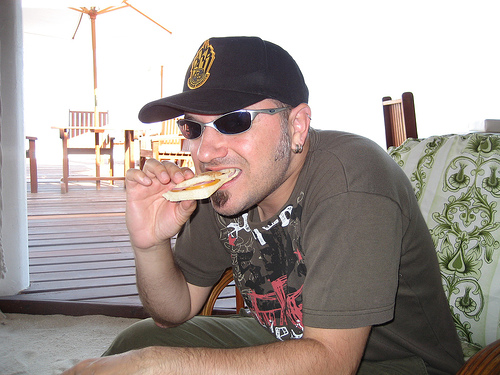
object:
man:
[60, 35, 463, 374]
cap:
[137, 36, 310, 124]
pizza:
[161, 169, 240, 202]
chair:
[60, 106, 116, 192]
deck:
[0, 177, 259, 313]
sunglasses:
[178, 108, 291, 139]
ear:
[290, 104, 312, 154]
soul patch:
[212, 191, 230, 207]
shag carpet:
[0, 313, 143, 375]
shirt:
[174, 128, 466, 371]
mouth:
[200, 167, 240, 184]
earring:
[295, 144, 305, 154]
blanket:
[387, 131, 499, 365]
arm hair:
[151, 344, 313, 372]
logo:
[185, 39, 217, 89]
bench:
[129, 121, 186, 178]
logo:
[213, 191, 305, 345]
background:
[0, 1, 499, 311]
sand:
[1, 312, 151, 372]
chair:
[204, 132, 499, 374]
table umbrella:
[68, 0, 175, 140]